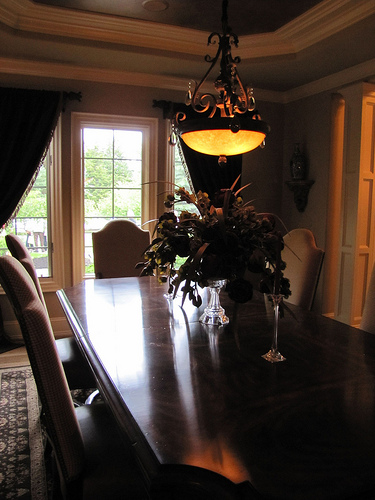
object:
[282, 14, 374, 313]
wall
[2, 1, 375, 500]
dining room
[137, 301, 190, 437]
shadow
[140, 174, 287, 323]
tree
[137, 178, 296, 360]
flower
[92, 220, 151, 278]
chair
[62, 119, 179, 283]
pink chair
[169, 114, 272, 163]
light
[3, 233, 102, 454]
chairs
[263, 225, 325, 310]
chairs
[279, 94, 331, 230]
wall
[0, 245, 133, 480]
chair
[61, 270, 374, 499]
desk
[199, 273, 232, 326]
vase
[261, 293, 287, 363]
candle holder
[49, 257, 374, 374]
table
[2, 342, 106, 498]
floor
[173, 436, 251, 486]
light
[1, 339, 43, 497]
floor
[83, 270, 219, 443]
reflection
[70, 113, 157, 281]
window